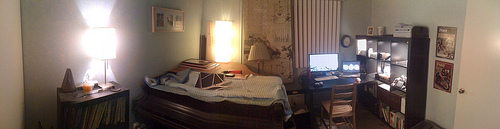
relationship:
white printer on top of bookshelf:
[393, 20, 428, 39] [354, 34, 429, 126]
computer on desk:
[307, 53, 339, 72] [283, 68, 375, 125]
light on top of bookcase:
[81, 27, 119, 59] [55, 80, 131, 127]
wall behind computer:
[291, 0, 340, 71] [306, 52, 350, 86]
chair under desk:
[319, 79, 361, 127] [300, 65, 385, 126]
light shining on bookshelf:
[357, 37, 367, 55] [354, 34, 429, 126]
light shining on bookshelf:
[378, 66, 390, 80] [354, 34, 429, 126]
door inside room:
[451, 0, 498, 127] [0, 1, 498, 127]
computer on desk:
[307, 51, 339, 74] [297, 67, 374, 121]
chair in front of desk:
[319, 79, 361, 127] [297, 69, 384, 126]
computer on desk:
[307, 53, 339, 72] [304, 65, 407, 100]